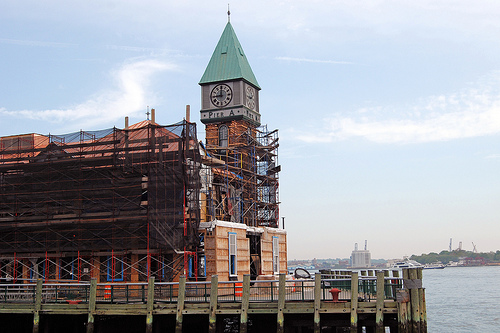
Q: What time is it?
A: 9:00.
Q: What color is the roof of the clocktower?
A: Green.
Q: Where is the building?
A: On the pier.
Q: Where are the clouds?
A: In the sky.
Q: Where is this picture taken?
A: The seaside.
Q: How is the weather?
A: Clear.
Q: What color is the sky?
A: Blue.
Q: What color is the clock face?
A: White.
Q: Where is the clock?
A: The tower.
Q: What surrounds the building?
A: Scaffolding.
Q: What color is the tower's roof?
A: Green.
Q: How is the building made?
A: Of brick.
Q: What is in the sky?
A: Clouds.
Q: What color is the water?
A: Blue.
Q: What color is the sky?
A: Blue.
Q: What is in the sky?
A: Clouds.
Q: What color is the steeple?
A: Green.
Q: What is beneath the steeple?
A: A clock.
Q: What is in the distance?
A: Buildings.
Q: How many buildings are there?
A: 1.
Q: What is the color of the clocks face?
A: White.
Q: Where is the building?
A: Next to water.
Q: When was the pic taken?
A: During the day.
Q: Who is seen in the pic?
A: No one.